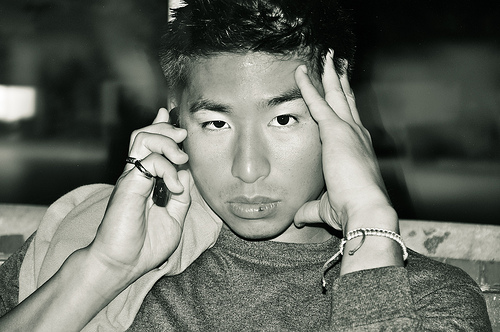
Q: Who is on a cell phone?
A: A boy.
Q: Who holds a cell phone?
A: A man.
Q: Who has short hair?
A: Boy.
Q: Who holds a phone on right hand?
A: A man.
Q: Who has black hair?
A: A man.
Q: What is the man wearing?
A: A gray top.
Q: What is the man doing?
A: Talking on the phone.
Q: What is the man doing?
A: Holding a cell phone.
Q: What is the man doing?
A: Listening on the phone.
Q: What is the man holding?
A: A phone.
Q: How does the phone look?
A: It is black.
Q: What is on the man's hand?
A: Two rings.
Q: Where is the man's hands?
A: On his face.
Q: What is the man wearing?
A: A black sweater.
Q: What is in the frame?
A: A man on a cell phone.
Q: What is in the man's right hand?
A: Phone.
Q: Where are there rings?
A: Right fingers.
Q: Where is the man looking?
A: At camera.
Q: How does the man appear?
A: Annoyed.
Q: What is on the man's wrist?
A: Bracelet.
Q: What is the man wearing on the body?
A: Sweatshirt.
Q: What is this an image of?
A: Man on phone.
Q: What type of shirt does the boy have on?
A: Long sleeve.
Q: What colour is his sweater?
A: Grey.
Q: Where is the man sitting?
A: Outside on a bench.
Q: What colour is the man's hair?
A: Black.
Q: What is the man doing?
A: Talking on the phone.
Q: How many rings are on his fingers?
A: Two.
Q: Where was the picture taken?
A: On the streets.